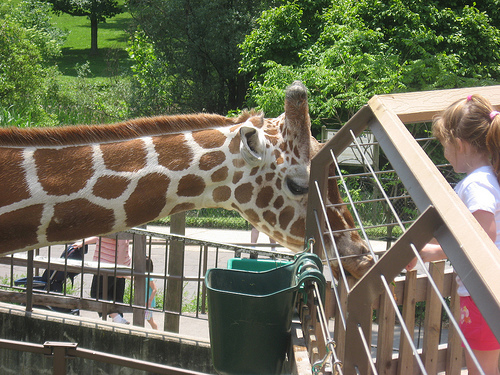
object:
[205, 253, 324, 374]
bins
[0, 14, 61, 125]
green trees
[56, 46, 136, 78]
shadow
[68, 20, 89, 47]
grass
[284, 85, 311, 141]
horns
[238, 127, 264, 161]
giraffe's ear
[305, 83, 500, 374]
railing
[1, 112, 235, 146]
hair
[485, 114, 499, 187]
ponytail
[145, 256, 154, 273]
hair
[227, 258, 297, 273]
bucket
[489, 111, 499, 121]
hair tie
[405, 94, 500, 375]
child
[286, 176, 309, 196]
giraffe's eye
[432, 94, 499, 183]
hair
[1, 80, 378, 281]
giraffe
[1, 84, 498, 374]
pen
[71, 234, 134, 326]
girl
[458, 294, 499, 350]
shorts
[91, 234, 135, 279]
shirt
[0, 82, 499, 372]
zoo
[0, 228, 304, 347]
fence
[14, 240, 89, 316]
stroller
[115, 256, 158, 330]
child